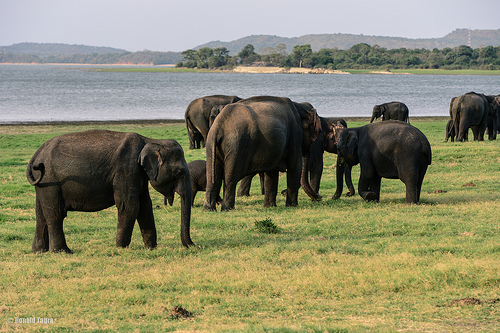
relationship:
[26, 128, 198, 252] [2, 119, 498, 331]
elephant standing on grass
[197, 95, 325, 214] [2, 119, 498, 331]
elephant standing in grass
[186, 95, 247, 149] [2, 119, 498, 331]
elephant standing in grass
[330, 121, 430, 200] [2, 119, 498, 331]
elephant standing in grass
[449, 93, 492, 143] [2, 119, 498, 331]
elephant standing in grass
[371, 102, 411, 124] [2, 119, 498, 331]
elephant standing on grass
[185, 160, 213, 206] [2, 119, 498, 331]
elephant standing on grass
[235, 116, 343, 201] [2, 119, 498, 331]
elephant standing on grass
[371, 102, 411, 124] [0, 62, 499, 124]
elephant near water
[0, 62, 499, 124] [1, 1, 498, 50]
water below sky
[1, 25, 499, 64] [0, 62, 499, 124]
hills are behind water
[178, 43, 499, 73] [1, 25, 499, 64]
trees in front of hills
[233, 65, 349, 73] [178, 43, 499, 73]
sand beneath trees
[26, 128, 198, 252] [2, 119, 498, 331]
elephant on grass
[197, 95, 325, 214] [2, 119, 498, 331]
elephant on grass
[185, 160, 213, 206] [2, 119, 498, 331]
elephant on grass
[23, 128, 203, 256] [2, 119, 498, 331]
elephant are on grass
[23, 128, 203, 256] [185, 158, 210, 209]
elephant have elephant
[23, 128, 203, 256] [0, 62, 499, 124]
elephant are beside water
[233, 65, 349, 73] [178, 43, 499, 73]
sand below trees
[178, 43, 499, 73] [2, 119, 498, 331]
trees are across from grass